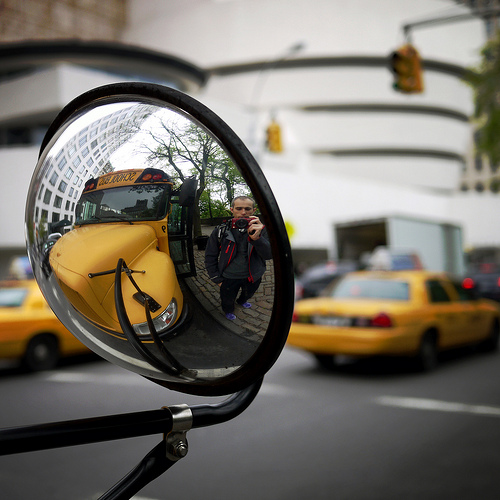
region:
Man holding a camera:
[231, 212, 256, 234]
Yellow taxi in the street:
[322, 257, 458, 392]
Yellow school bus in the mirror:
[49, 154, 211, 340]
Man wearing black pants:
[211, 260, 270, 309]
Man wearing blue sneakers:
[221, 294, 259, 334]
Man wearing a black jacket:
[213, 220, 256, 290]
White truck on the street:
[341, 197, 488, 312]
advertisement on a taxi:
[361, 231, 437, 288]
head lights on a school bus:
[140, 309, 188, 339]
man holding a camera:
[207, 194, 274, 360]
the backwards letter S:
[128, 170, 139, 185]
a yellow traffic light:
[375, 39, 447, 121]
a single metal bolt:
[164, 434, 201, 460]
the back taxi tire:
[412, 320, 454, 375]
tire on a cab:
[17, 329, 69, 382]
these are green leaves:
[464, 46, 499, 163]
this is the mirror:
[13, 52, 333, 497]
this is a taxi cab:
[267, 255, 499, 377]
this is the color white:
[316, 76, 340, 91]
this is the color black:
[211, 408, 221, 415]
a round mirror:
[23, 91, 295, 400]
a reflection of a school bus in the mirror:
[42, 168, 198, 337]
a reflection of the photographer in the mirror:
[204, 195, 273, 320]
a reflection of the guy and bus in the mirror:
[51, 165, 268, 342]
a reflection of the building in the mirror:
[31, 103, 161, 170]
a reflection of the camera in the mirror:
[229, 216, 250, 233]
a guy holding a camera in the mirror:
[204, 194, 270, 322]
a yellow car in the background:
[296, 247, 498, 375]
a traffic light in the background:
[384, 42, 424, 95]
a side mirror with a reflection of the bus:
[3, 80, 295, 446]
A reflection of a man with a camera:
[206, 183, 265, 338]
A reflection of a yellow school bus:
[49, 132, 191, 344]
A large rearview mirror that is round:
[37, 115, 291, 386]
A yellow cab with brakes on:
[276, 224, 491, 362]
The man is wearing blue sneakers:
[197, 184, 284, 322]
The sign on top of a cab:
[366, 248, 431, 276]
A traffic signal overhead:
[251, 108, 288, 154]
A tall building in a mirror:
[48, 102, 136, 227]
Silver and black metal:
[128, 405, 192, 465]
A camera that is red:
[225, 210, 258, 237]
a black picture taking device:
[232, 214, 253, 235]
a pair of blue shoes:
[219, 300, 251, 320]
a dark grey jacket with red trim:
[203, 220, 271, 285]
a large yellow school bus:
[48, 168, 199, 353]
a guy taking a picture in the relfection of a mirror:
[203, 192, 275, 323]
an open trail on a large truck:
[322, 217, 474, 274]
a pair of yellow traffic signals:
[255, 36, 427, 161]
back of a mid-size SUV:
[462, 253, 498, 295]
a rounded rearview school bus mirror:
[24, 80, 292, 430]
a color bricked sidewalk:
[179, 220, 272, 342]